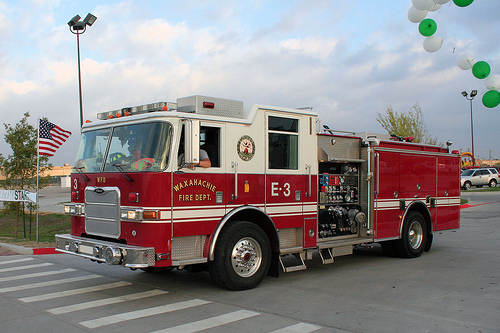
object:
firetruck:
[52, 93, 461, 291]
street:
[1, 187, 500, 332]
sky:
[0, 0, 500, 162]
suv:
[460, 167, 500, 192]